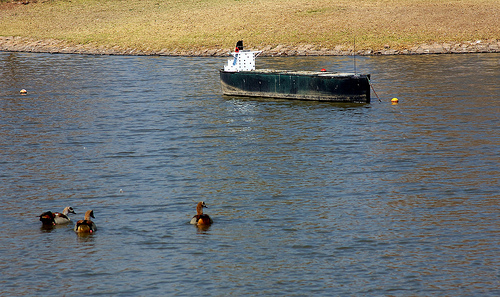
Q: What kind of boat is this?
A: Tanker.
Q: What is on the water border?
A: Rocks.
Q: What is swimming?
A: Ducks.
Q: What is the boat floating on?
A: Water.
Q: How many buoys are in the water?
A: Two.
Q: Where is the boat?
A: In the water.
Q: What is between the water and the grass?
A: Stones.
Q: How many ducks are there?
A: Three.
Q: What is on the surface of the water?
A: Waves.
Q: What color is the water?
A: Blue.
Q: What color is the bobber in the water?
A: Yellow and red.